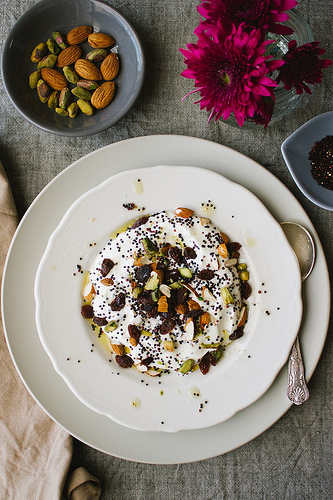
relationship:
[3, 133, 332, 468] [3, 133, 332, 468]
plate on plate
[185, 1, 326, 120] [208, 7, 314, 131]
flowers are in jar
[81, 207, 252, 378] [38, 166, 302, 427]
dessert in bowl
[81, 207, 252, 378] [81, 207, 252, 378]
dessert in dessert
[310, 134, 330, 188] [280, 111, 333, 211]
poppy seeds in bowl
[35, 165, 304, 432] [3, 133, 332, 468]
bowl on plate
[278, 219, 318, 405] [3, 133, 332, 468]
spoon on plate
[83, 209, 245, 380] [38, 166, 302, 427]
dessert in bowl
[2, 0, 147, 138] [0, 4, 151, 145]
almonds/pistachios/bowl in bowl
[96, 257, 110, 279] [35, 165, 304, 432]
raisin on bowl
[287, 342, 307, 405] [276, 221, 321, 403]
design on end of spoon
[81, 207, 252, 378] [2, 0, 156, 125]
dessert on bowl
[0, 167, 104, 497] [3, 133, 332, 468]
napkin under plate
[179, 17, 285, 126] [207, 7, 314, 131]
flowers in jar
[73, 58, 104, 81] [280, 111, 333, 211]
almonds in bowl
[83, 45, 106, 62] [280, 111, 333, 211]
pistachios in bowl